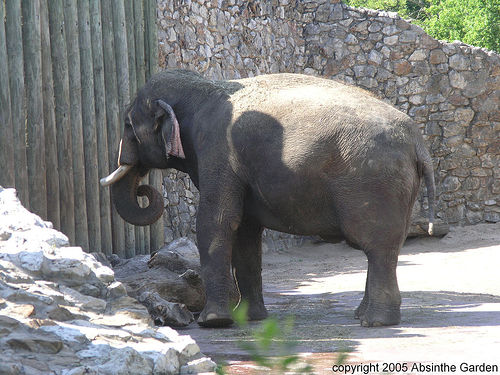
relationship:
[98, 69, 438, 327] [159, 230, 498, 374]
elephant on ground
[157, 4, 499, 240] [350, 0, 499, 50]
wall below trees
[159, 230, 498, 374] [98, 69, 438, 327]
ground below elephant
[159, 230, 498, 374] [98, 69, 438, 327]
ground under elephant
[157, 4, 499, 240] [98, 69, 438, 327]
wall near elephant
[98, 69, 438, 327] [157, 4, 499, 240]
elephant near wall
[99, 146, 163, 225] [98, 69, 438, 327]
trunk of an elephant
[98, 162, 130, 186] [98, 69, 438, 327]
tusk of an elephant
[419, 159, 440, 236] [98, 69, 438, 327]
tail of an elephant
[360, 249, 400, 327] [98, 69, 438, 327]
legs of an elephant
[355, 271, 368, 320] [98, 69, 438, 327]
legs of an elephant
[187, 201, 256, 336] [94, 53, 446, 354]
leg on elephant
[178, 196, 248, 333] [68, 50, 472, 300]
leg on elephant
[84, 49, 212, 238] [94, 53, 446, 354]
head on elephant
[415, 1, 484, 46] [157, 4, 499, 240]
trees behind wall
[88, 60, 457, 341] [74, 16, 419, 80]
elephant in enclosure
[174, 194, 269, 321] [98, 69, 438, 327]
leg on elephant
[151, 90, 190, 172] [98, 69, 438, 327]
ear on elephant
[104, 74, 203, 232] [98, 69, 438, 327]
head on elephant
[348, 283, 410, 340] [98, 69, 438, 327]
foot on elephant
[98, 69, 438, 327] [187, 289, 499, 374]
elephant on ground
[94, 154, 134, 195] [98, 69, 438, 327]
tusk on elephant